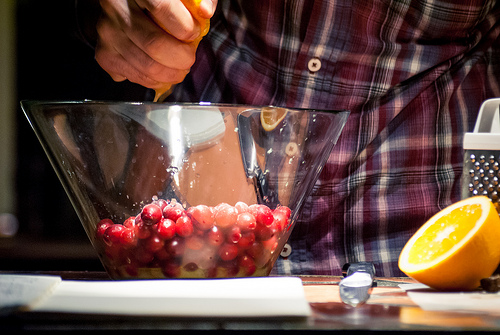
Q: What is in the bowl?
A: Cranberries.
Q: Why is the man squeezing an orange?
A: To get the juice.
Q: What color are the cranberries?
A: Red.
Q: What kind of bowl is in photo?
A: Glass.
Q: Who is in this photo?
A: A man.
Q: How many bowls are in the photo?
A: One.